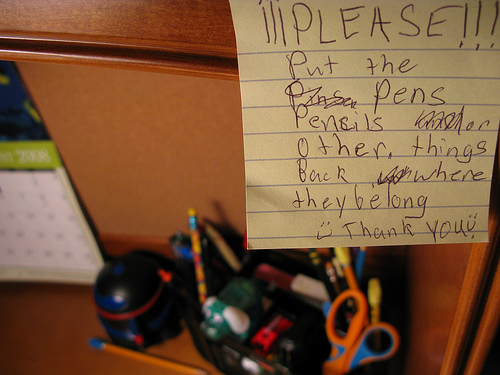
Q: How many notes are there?
A: One.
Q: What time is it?
A: 8:00 a.m.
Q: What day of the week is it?
A: Friday.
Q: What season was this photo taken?
A: Spring.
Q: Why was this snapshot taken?
A: To show the principal.